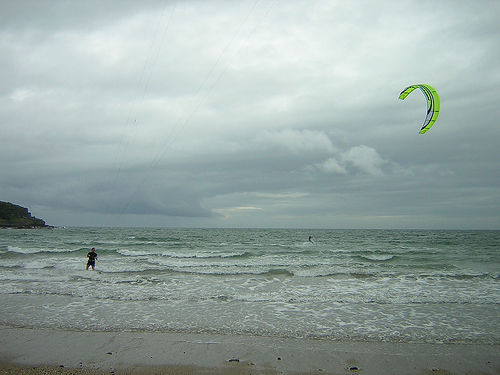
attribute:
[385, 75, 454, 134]
kite — green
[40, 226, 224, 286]
water — blue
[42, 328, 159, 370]
sand — wet, brown, void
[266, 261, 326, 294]
waves — crashing, white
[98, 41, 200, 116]
clouds — dark, fluffy, gre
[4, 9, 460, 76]
sky — grey, cloudy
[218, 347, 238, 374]
rock — small